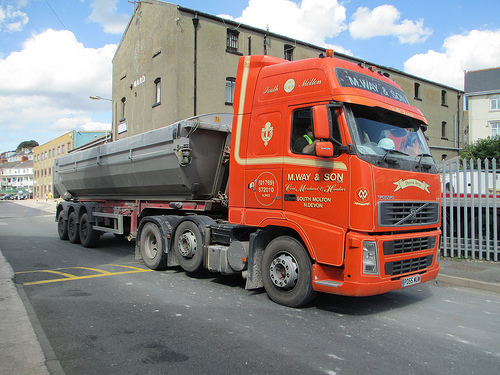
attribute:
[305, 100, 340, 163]
mirrors — side-view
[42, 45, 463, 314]
truck — industrial, large, orange, grey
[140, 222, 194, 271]
tires — black, large, big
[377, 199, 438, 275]
grilles — black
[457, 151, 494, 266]
fence — white, tall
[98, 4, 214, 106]
building — tall, brown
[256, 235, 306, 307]
tire — black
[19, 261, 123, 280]
lines — yellow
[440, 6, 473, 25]
sky — blue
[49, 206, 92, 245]
wheels — black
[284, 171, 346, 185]
letters — yellow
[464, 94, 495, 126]
building — white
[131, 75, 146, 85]
letters — white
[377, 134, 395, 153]
hat — white, hard